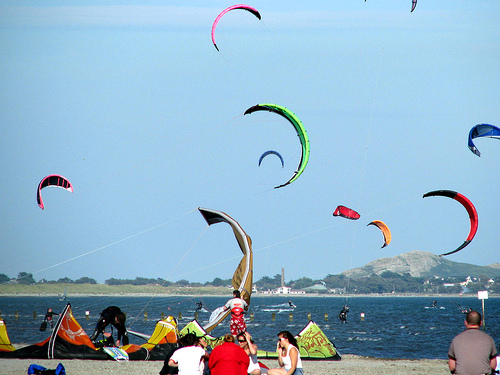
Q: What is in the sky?
A: Kites.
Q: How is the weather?
A: Clear.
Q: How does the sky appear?
A: Blue and clear.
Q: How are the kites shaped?
A: As half moons.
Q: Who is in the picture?
A: Men and women.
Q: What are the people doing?
A: Flying kites.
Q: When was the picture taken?
A: Afternoon.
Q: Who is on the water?
A: Parasailers.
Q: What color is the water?
A: Blue.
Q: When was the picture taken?
A: Afternoon.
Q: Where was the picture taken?
A: Beach.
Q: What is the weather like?
A: Sunny.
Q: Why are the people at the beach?
A: Fun.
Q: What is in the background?
A: Horizon.